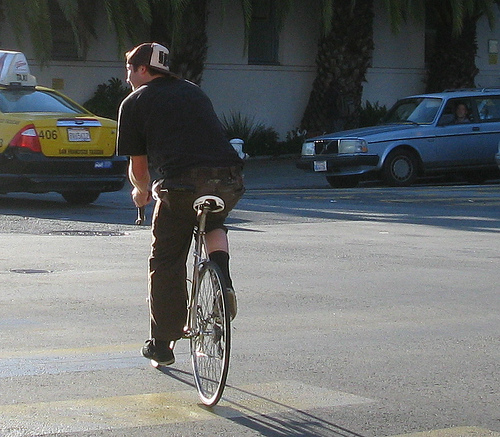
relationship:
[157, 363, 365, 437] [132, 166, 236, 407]
shadow of bicycle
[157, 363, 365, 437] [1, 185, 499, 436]
shadow on pavement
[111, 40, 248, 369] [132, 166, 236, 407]
guy riding a bicycle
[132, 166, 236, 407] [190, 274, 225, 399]
bicycle has wheel spokes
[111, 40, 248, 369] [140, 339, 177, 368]
man has a shoe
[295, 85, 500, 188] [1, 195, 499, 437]
car at intersection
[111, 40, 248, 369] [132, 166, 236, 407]
person riding a bicycle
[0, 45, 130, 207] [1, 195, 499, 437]
taxi cab on street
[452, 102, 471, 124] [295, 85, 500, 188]
person driving a car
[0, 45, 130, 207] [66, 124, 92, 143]
taxi cab has a license plate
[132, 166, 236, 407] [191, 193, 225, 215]
bicycle has a seat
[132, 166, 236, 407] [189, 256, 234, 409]
bicycle has a back tire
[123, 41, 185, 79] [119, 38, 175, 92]
cap on person's head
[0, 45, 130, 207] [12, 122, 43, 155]
taxi cab has tail light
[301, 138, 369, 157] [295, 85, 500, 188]
headlights on front of car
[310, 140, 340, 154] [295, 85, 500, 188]
gril on front of car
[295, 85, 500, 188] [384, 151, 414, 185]
car has a tire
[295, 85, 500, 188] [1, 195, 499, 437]
car on road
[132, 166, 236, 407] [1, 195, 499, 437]
bicycle on road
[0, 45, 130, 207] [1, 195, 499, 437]
taxi on road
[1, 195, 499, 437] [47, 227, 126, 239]
road has manhole cover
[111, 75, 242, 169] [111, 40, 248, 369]
shirt on man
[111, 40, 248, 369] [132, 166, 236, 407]
man on bicycle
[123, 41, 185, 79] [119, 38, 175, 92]
cap on man's head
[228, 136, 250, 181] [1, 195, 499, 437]
fire hydrant alongside road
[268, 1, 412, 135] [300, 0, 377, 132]
tree has a trunk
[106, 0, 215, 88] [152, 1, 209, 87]
tree has a trunk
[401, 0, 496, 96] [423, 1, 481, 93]
tree has a trunk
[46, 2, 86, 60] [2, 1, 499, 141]
window in building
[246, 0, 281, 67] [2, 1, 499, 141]
window in building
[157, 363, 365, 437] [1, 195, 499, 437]
shadow on street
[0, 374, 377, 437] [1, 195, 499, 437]
line on street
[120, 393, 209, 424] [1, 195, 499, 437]
smudge on street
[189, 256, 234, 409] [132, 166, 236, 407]
wheel on bike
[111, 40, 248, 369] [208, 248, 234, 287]
man wearing sock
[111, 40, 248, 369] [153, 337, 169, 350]
man wearing sock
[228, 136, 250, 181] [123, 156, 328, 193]
fire hydrant on side walk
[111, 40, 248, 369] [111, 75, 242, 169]
man wearing shirt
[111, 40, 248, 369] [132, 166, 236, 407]
man riding bike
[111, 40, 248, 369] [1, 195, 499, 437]
man on street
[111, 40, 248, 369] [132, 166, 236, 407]
man riding a bicycle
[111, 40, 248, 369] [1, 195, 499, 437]
man in street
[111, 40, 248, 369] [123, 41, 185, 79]
man wearing a cap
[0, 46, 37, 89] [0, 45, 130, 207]
sign mounted on car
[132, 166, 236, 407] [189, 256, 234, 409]
bicycle has a rear tire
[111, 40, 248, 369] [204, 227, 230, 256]
man has a bare leg